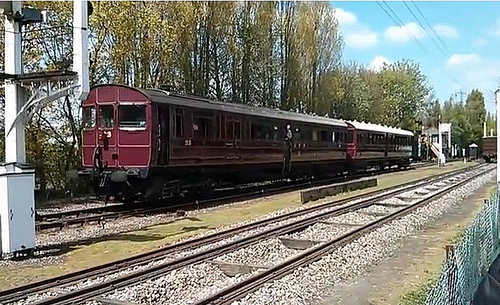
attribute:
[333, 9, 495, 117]
clouds — white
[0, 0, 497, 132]
sky — blue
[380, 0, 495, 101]
lines — overhead, utility lines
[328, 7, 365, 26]
cloud — white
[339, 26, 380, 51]
cloud — white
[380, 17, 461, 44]
cloud — white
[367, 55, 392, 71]
cloud — white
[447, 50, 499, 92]
cloud — white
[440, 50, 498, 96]
clouds — white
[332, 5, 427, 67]
clouds — white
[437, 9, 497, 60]
clouds — white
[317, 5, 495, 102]
sky — blue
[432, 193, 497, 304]
fence — green, mesh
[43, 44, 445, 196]
train — red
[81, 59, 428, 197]
train — red 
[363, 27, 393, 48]
clouds — white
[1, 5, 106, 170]
light train — red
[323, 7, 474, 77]
clouds — white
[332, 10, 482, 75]
sky — blue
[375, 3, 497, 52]
sky — blue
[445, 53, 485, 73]
cloud — white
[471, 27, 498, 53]
cloud — white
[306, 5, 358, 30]
cloud — white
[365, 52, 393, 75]
cloud — white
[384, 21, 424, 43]
cloud — white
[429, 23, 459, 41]
cloud — white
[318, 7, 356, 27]
cloud — white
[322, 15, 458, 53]
clouds — white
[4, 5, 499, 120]
clouds — white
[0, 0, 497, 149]
sky — blue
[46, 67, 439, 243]
train — burgundy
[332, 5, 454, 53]
clouds — white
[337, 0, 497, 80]
sky — blue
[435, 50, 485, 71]
cloud — white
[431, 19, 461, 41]
cloud — white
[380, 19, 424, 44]
cloud — white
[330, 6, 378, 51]
cloud — white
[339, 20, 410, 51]
clouds — white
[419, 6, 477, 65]
sky — blue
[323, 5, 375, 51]
cloud — white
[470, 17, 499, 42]
cloud — white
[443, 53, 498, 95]
cloud — white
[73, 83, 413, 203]
train — burgundy, black, brown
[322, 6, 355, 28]
cloud — white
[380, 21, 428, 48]
cloud — white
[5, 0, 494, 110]
sky — blue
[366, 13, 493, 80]
clouds — white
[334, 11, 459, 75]
sky — blue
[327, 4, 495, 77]
sky — blue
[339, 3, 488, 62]
sky — blue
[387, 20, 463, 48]
clouds — white